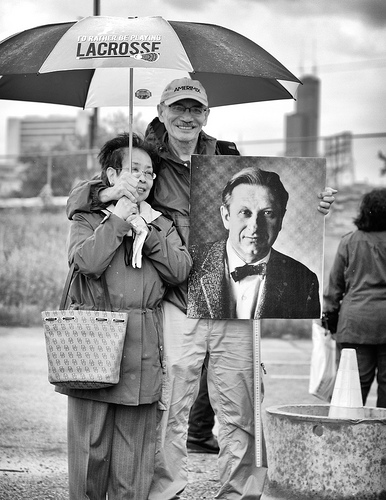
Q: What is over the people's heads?
A: Umbrella.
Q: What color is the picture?
A: Black and white.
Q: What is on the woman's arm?
A: A purse.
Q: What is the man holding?
A: A picture.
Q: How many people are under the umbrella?
A: 2.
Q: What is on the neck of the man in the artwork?
A: A tie.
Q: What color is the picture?
A: Black and white.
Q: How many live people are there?
A: Three.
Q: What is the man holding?
A: A portrait.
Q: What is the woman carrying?
A: A purse.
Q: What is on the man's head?
A: A hat.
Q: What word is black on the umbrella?
A: Lacrosse.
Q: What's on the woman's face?
A: Glasses.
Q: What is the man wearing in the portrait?
A: A tux.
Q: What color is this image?
A: Black and white.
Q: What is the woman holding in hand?
A: Umbrella.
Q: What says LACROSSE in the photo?
A: Umbrella.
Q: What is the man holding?
A: Photo.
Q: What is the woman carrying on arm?
A: Purse.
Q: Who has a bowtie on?
A: Man in the picture.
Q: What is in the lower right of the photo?
A: Metal container.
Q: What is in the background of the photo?
A: Buildings.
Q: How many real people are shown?
A: 3.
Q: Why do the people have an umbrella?
A: To stay dry.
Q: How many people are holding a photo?
A: 1.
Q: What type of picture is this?
A: Black and white.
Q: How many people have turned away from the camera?
A: 1.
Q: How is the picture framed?
A: It isn't framed.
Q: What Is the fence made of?
A: Chain Link.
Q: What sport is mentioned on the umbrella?
A: Lacrosse.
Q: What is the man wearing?
A: A baseball cap.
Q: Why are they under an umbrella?
A: It's raining.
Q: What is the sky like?
A: Cloudy.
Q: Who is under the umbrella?
A: A man and a woman.